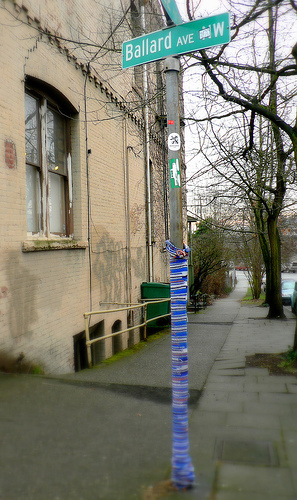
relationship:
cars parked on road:
[259, 270, 295, 316] [226, 269, 296, 311]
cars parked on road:
[229, 260, 296, 272] [226, 269, 296, 311]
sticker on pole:
[166, 131, 181, 150] [159, 56, 195, 487]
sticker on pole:
[166, 119, 175, 124] [159, 56, 195, 487]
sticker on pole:
[166, 157, 181, 188] [159, 56, 195, 487]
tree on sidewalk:
[179, 0, 297, 320] [65, 276, 287, 496]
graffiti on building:
[85, 226, 148, 303] [0, 0, 188, 377]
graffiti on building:
[5, 254, 43, 338] [0, 0, 188, 377]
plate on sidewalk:
[212, 434, 281, 465] [1, 273, 295, 497]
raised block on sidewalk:
[213, 361, 246, 368] [59, 274, 249, 389]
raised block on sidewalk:
[212, 353, 239, 361] [59, 274, 249, 389]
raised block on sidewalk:
[210, 366, 245, 375] [59, 274, 249, 389]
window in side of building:
[22, 84, 74, 239] [0, 0, 188, 377]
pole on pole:
[164, 56, 196, 487] [162, 239, 192, 487]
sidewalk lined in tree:
[149, 250, 289, 418] [222, 24, 287, 318]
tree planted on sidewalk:
[179, 0, 294, 320] [1, 273, 295, 497]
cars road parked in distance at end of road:
[233, 259, 249, 278] [228, 267, 287, 288]